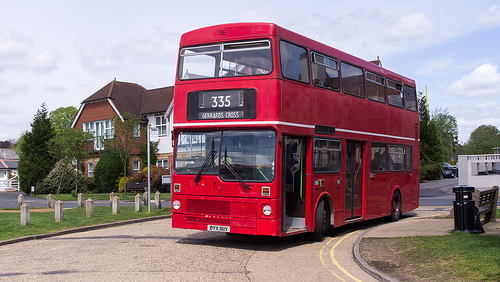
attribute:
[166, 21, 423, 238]
bus — red , bi-level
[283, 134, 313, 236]
door — open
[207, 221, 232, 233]
plate — white 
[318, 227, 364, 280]
line — yellow 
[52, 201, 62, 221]
post — short 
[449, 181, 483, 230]
receptacle — black 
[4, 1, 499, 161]
sky — blue 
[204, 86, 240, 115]
numbers — white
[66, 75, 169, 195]
house — brick, red, white, brown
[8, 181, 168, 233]
posts — grey, white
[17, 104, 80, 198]
trees — tall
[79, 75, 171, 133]
roof — dark brown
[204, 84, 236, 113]
number — white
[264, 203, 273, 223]
light — white, round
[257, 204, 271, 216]
light — round, white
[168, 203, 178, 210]
light — round, white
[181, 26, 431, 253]
bus — red, double decker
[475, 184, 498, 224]
bench — black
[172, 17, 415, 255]
bus — double decker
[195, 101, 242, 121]
text — small